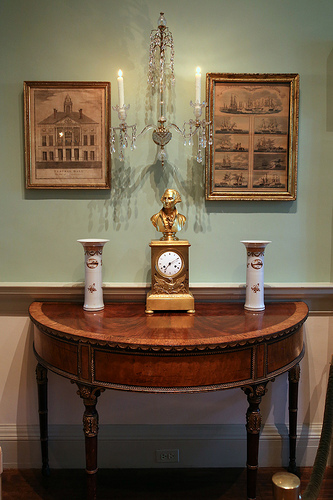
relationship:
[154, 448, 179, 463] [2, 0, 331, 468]
outlet in wall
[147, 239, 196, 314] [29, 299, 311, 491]
clock on table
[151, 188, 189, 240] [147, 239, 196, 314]
statue on clock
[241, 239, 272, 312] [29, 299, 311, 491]
vase on table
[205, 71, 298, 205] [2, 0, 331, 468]
picture on wall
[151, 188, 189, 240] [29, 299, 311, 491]
statue on table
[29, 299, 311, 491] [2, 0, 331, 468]
table against wall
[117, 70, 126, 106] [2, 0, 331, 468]
candle in front of wall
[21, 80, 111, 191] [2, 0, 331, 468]
picture on wall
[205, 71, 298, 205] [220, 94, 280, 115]
picture of ships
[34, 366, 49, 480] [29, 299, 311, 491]
leg of table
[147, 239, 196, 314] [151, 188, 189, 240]
clock under statue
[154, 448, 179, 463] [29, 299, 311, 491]
outlet under table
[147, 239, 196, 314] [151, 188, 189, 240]
clock with statue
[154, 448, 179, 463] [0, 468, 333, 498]
outlet near floor